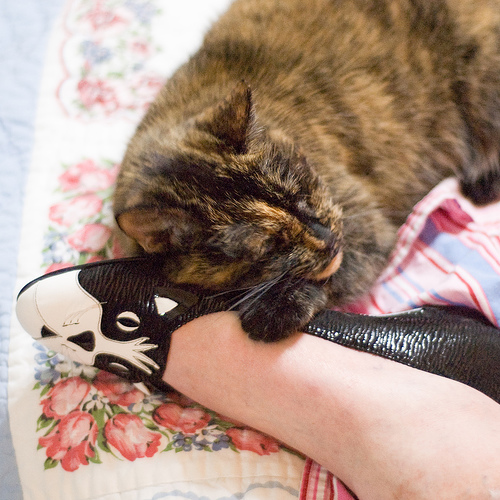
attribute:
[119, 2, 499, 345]
cat — tabby, sleeping, resting, multicolored, touching, pretty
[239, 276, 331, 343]
paw — dark, touching, resting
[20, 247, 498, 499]
foot — pale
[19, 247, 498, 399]
shoe — black, leather, slipped on, white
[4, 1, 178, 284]
sheet — printed, floral, striped, patterned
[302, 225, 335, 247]
nose — dark